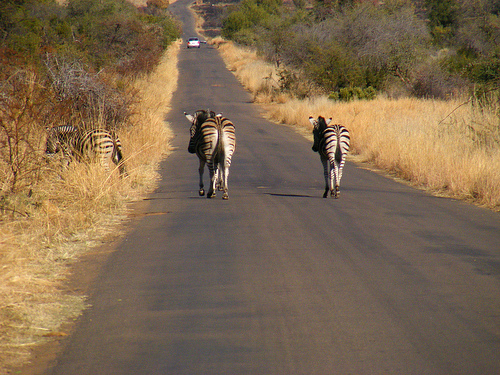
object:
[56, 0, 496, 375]
road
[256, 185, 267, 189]
dark spot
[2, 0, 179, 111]
trees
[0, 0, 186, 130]
shrub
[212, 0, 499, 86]
shrub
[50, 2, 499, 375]
concrete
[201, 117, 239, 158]
rear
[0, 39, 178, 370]
grass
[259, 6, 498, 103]
overgrowth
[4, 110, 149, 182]
zebra road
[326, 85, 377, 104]
bushes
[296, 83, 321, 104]
plants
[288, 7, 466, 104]
trees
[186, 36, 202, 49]
car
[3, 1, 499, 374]
outside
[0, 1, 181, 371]
side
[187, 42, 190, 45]
lights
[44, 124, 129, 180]
zebra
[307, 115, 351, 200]
zebra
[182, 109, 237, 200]
zebra